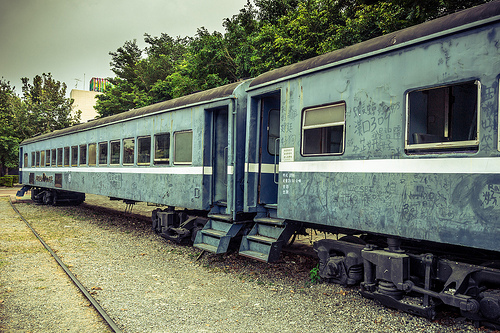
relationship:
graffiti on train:
[373, 190, 488, 237] [251, 62, 499, 248]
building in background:
[76, 78, 127, 106] [13, 46, 37, 59]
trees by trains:
[250, 34, 318, 72] [78, 106, 401, 247]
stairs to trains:
[202, 211, 281, 261] [78, 106, 401, 247]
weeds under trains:
[297, 257, 330, 277] [78, 106, 401, 247]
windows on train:
[23, 142, 204, 165] [251, 62, 499, 248]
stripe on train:
[282, 153, 487, 203] [251, 62, 499, 248]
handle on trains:
[269, 138, 280, 176] [78, 106, 401, 247]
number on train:
[363, 102, 395, 141] [251, 62, 499, 248]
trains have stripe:
[78, 106, 401, 247] [282, 153, 487, 203]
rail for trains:
[60, 270, 102, 309] [78, 106, 401, 247]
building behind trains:
[76, 78, 127, 106] [78, 106, 401, 247]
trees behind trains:
[250, 34, 318, 72] [78, 106, 401, 247]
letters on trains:
[273, 176, 288, 190] [78, 106, 401, 247]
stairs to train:
[202, 211, 281, 261] [251, 62, 499, 248]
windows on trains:
[23, 142, 204, 165] [78, 106, 401, 247]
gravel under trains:
[104, 240, 169, 299] [78, 106, 401, 247]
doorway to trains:
[196, 111, 236, 212] [78, 106, 401, 247]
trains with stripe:
[78, 106, 401, 247] [282, 153, 487, 203]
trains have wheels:
[78, 106, 401, 247] [317, 245, 393, 312]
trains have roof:
[78, 106, 401, 247] [328, 45, 371, 71]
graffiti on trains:
[373, 190, 488, 237] [78, 106, 401, 247]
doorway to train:
[196, 111, 236, 212] [251, 62, 499, 248]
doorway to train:
[248, 96, 277, 237] [251, 62, 499, 248]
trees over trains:
[250, 34, 318, 72] [78, 106, 401, 247]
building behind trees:
[76, 78, 127, 106] [250, 34, 318, 72]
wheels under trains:
[317, 245, 393, 312] [78, 106, 401, 247]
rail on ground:
[60, 270, 102, 309] [32, 281, 59, 309]